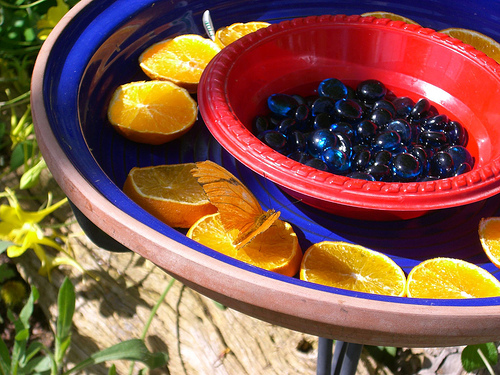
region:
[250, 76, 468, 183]
shiny blue glass beads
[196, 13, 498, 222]
red styrofoam disposable bowl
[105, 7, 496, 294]
slices of ripe oranges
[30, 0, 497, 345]
porcelain bowl with blue center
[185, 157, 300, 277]
orange butterfly on fruit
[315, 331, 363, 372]
part of metal stand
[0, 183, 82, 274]
yellow bloom of flower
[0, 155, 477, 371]
wooden base under tray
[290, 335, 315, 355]
small hole in wood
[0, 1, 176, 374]
greenery next to wood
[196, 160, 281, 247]
butterfly sitting on an orange slice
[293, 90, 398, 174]
blue glass marbles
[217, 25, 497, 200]
red plastic bowl with blue glass stones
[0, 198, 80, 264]
yellow flower in the background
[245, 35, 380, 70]
red plastic bowl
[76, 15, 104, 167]
blue ceramic standing bowl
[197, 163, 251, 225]
butterfly wing with a dark stripe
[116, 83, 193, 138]
sliced orange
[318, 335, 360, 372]
metal stand for the feeder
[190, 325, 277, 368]
wooden log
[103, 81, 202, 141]
half a orange in plate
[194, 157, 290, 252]
orange butterfly sitting on orange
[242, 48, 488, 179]
blue glass beads in bowl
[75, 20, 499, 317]
cut up oranges in plate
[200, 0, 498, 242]
red bowl with beads in it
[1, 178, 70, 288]
little yellow flower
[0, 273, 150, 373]
green weeds shrubs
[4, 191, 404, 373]
wooden log with weeds and flowers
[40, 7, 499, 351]
blue ceramic plate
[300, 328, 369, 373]
blue table leg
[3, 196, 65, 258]
beautiful yellow flower petal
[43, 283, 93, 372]
green blade of grass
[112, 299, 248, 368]
portion of tan wood stump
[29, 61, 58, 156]
edge of plate with tan color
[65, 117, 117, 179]
deep blue plate with yellow inside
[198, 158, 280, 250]
orange butterfly resting on fruit slice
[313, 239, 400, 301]
round slice of cut orange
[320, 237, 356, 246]
white rind on orange slice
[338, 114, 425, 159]
shiny blueberries in bowl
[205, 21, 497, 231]
deep red bowl with intricate edges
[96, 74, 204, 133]
a slice of an orange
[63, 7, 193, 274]
orange slices on blue plate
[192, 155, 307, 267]
orange butterfly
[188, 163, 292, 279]
butterfly on a slice of an orange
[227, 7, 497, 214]
a red bowl with blue glass stones in it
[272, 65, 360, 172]
blue glass stones shining in the sun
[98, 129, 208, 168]
grooves in a bowl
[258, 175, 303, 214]
antennae of a butterfly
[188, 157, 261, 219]
orange butterfly wing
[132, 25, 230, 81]
sunlight shining on an orange slice